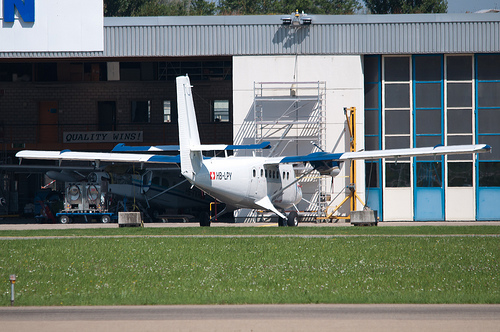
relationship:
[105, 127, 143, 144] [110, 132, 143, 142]
print reading print